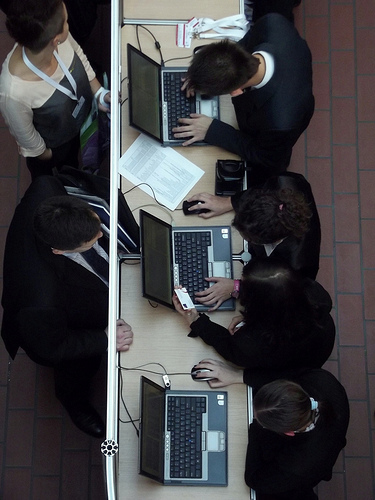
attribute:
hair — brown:
[1, 4, 82, 63]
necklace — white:
[21, 47, 86, 118]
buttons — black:
[171, 406, 199, 463]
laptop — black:
[132, 205, 241, 315]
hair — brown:
[33, 191, 104, 252]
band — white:
[12, 30, 106, 132]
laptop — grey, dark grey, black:
[124, 40, 220, 148]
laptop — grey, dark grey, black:
[135, 209, 236, 313]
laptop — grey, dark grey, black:
[137, 374, 226, 487]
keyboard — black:
[163, 72, 199, 148]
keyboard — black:
[174, 229, 213, 301]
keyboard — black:
[169, 395, 208, 476]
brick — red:
[325, 37, 363, 188]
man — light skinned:
[170, 12, 315, 168]